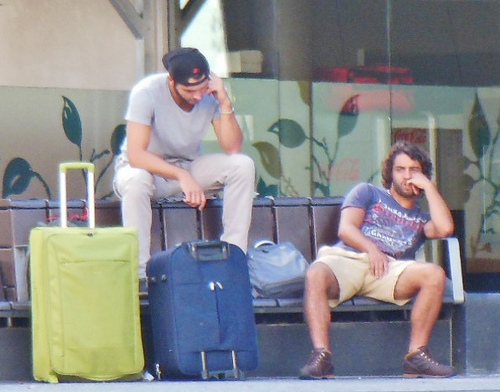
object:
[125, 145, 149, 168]
elbow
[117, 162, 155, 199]
knee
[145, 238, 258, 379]
suitcase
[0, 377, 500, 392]
ground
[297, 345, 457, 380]
shoes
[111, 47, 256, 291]
man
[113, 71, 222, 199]
gray shirt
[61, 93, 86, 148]
leave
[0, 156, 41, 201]
leave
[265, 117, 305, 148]
leave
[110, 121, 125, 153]
leave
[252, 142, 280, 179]
leave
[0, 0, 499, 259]
wall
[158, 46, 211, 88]
backwards hat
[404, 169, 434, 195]
hand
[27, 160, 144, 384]
suitcase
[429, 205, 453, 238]
elbow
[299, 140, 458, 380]
man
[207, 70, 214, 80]
cellphone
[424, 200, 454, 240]
arm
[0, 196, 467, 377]
bench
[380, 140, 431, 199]
head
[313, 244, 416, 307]
shorts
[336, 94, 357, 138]
leaves